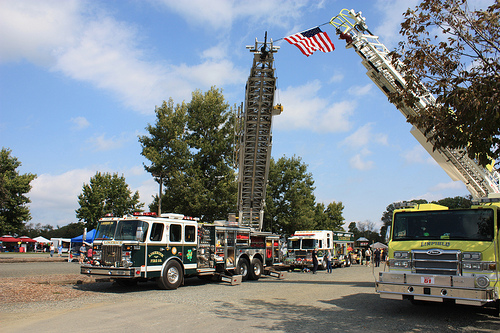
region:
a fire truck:
[77, 198, 298, 295]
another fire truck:
[359, 188, 497, 318]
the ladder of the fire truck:
[225, 30, 295, 227]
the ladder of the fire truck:
[335, 6, 497, 211]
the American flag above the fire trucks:
[266, 8, 354, 69]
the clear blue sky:
[24, 77, 59, 139]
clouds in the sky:
[37, 7, 120, 102]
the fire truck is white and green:
[101, 226, 216, 286]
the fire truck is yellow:
[386, 201, 496, 308]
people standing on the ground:
[303, 246, 382, 270]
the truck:
[13, 157, 340, 329]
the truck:
[44, 200, 193, 324]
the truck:
[114, 140, 246, 324]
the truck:
[69, 103, 205, 300]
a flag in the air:
[252, 0, 417, 95]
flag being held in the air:
[221, 0, 467, 129]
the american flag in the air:
[264, 11, 486, 131]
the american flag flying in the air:
[257, 4, 413, 129]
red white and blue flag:
[251, 5, 412, 81]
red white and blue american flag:
[236, 3, 425, 101]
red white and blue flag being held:
[244, 10, 497, 136]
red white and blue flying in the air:
[236, 25, 481, 127]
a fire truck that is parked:
[87, 0, 407, 274]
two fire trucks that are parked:
[144, 37, 495, 281]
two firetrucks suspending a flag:
[66, 10, 497, 312]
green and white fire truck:
[72, 217, 283, 289]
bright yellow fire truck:
[362, 197, 499, 304]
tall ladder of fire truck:
[233, 36, 283, 236]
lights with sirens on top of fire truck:
[128, 207, 166, 220]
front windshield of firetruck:
[388, 206, 497, 246]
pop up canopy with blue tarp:
[67, 226, 106, 263]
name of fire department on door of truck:
[145, 249, 165, 266]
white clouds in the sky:
[44, 32, 157, 95]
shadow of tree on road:
[206, 293, 368, 330]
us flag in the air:
[259, 10, 367, 65]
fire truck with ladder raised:
[73, 29, 304, 301]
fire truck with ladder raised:
[326, 5, 498, 314]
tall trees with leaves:
[139, 88, 235, 213]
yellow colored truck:
[371, 194, 497, 317]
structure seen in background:
[3, 225, 102, 260]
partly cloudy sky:
[0, 1, 157, 178]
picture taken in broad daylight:
[3, 3, 480, 308]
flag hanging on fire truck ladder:
[244, 5, 444, 135]